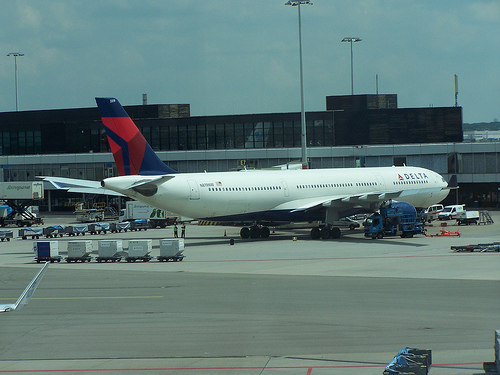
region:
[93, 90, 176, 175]
Blue tail fin of a plane with red arrow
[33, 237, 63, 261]
White luggage car with blue stripe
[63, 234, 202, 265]
White luggage car train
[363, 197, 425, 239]
Blue truck in front of plane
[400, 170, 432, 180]
Word DELTA written on plane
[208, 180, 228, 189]
American flag on a plane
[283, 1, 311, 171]
Light pole in an airport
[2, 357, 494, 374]
Red stripe on a runway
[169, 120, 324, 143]
Windows in a building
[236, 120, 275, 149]
Reflection of plane in glass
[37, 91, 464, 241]
Airplane in airport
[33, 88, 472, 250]
Airplane is fro passengers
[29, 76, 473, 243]
Airplane is white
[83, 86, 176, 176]
Vertical stabilizer is red and blue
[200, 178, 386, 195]
Small windows on side of airplane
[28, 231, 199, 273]
Five carts on side of airplane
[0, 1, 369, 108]
Light poles in airport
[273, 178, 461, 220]
Wing of plane is white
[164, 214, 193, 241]
Two people stand below plane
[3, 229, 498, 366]
Surface of plane is concrete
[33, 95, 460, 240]
A very large commercial airplane.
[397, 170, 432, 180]
The logo of the airplane company Delta.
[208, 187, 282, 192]
Some of the windows of this commercial aircraft.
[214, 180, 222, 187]
The American flag on the side of the plane.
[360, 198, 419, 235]
One of the propelling engines of this aircraft.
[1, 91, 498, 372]
An airport made for airplanes to land in.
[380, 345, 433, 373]
Some of the luggages used by passengers.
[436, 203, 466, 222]
A small van used for transportation.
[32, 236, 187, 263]
Six squared containers containing several items.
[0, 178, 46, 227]
Vehicle used to get passengers off the plane.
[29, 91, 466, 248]
a white airplane with red and blue tail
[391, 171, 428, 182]
an airplane carrier logo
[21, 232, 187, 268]
a string of luggage carts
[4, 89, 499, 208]
an airport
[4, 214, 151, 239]
a string of luggage carts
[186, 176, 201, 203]
an airplane exit hatch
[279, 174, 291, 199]
an airplane exit hatch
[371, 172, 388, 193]
an airplane exit hatch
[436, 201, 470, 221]
a white and red van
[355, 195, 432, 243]
a blue airplane jet engine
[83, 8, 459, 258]
large plane parked at airport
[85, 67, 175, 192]
geometric design on tail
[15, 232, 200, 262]
luggage carts aligned in a row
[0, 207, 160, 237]
covered short and wide carts behind plane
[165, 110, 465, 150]
dark glass panels on building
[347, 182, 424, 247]
blue service vehicle under wing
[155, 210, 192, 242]
two airport employees standing under plane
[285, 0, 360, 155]
tall light fixtures by airport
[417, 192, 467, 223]
white and orange vehicles near front of plane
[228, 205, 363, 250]
black wheels under the airplane